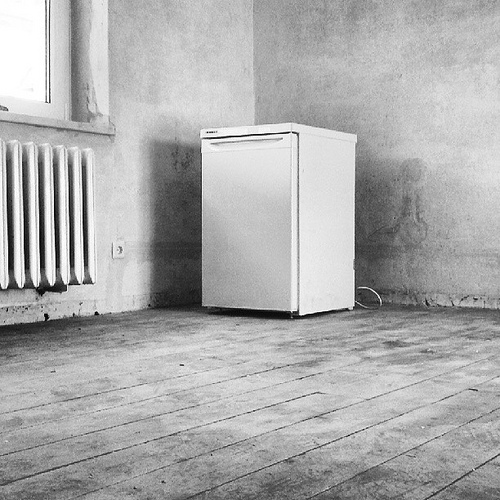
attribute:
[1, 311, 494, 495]
floor — wood, dirty, wooden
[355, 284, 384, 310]
wire — white, large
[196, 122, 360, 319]
fridge — white, small, large, mini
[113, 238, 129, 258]
outlet — white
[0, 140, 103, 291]
radiator — heated, white, attached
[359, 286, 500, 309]
paint — chipped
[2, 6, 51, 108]
window — glass, bright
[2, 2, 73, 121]
frame — white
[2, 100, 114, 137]
sill — white, large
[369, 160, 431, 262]
wall — stained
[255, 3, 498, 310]
wall — behind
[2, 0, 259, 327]
wall — below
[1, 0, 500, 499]
picture — black, white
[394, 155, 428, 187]
spot — black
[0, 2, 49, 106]
glass — clear